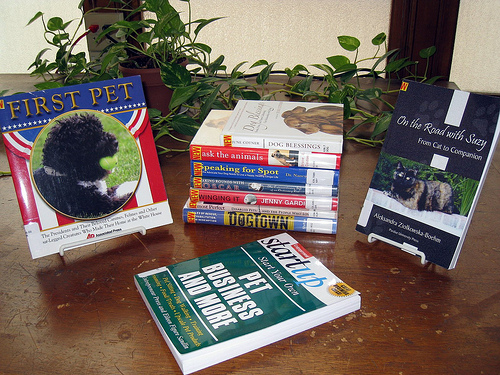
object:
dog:
[32, 112, 133, 218]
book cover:
[0, 75, 173, 260]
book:
[355, 79, 500, 270]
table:
[1, 73, 500, 374]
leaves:
[12, 0, 444, 155]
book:
[0, 75, 173, 260]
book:
[221, 100, 344, 154]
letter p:
[89, 88, 102, 106]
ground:
[0, 74, 500, 317]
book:
[134, 232, 362, 375]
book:
[182, 209, 336, 234]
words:
[178, 262, 273, 329]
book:
[190, 110, 341, 169]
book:
[191, 188, 338, 211]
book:
[190, 160, 338, 186]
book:
[191, 176, 338, 197]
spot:
[118, 330, 133, 340]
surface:
[2, 72, 498, 375]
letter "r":
[32, 96, 52, 114]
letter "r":
[294, 201, 299, 206]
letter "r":
[424, 122, 433, 134]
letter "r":
[206, 310, 232, 324]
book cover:
[354, 78, 498, 270]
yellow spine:
[224, 211, 294, 230]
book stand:
[86, 228, 122, 239]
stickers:
[329, 282, 355, 297]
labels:
[177, 262, 273, 330]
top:
[7, 81, 135, 120]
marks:
[362, 269, 452, 349]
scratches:
[55, 259, 157, 310]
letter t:
[118, 82, 133, 100]